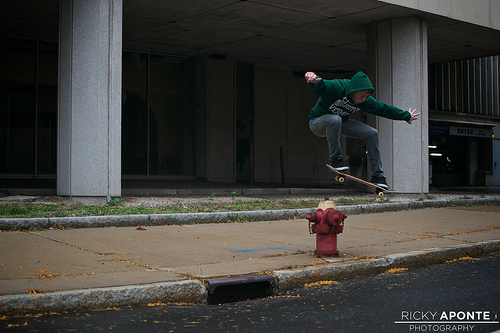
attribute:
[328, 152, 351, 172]
shoe — black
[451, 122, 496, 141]
sign — blue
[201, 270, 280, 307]
storm drain — metal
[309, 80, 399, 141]
sweatshirt — green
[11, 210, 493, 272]
sidewalk — cement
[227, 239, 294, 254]
paint — blue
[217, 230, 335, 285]
line — blue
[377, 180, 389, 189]
shoe — black, white